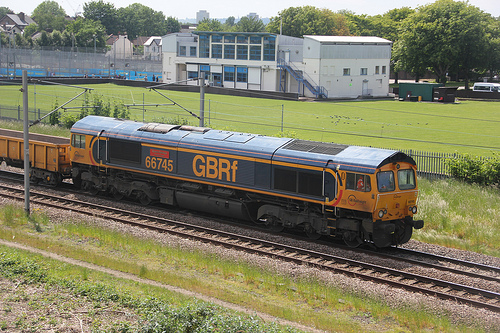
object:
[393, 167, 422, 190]
windows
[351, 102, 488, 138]
lawn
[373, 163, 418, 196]
windshield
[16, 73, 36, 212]
pole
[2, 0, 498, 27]
sky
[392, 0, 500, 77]
leaves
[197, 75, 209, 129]
poles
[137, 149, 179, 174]
number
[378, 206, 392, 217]
lights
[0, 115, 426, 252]
train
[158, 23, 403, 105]
building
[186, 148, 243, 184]
lettering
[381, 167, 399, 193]
window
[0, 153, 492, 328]
gravel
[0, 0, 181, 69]
trees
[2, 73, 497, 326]
grass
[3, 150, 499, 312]
train tracks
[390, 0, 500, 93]
trees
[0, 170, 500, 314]
tracks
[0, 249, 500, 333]
ground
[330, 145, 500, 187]
fence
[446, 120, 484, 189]
bushes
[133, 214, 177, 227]
plank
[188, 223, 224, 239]
plank